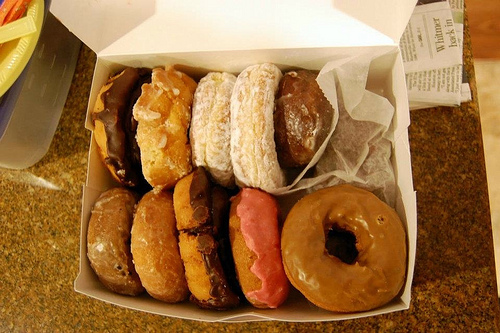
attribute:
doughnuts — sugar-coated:
[188, 63, 286, 194]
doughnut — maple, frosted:
[267, 179, 415, 330]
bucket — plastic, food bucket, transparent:
[0, 0, 79, 182]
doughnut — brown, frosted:
[279, 182, 406, 308]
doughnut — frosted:
[230, 184, 285, 310]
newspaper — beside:
[411, 9, 472, 129]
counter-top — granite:
[0, 0, 499, 331]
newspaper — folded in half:
[397, 2, 470, 109]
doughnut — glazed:
[83, 197, 136, 294]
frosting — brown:
[280, 187, 413, 306]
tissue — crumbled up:
[320, 57, 392, 184]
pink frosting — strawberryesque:
[237, 182, 287, 309]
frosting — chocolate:
[90, 64, 150, 189]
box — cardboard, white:
[48, 3, 422, 332]